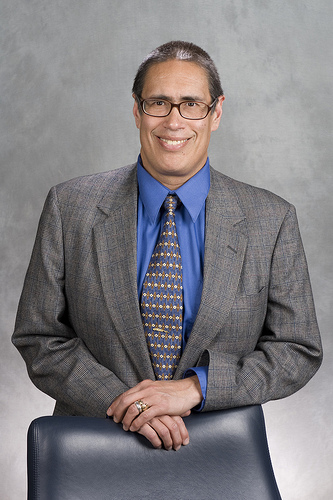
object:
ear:
[133, 101, 141, 129]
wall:
[0, 2, 330, 497]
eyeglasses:
[135, 95, 218, 120]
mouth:
[154, 134, 194, 150]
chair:
[26, 405, 280, 499]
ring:
[135, 401, 143, 412]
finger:
[113, 389, 145, 423]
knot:
[164, 195, 177, 212]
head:
[133, 41, 225, 176]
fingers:
[107, 381, 143, 416]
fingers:
[171, 415, 189, 445]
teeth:
[160, 137, 187, 145]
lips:
[156, 136, 191, 150]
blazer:
[12, 159, 324, 417]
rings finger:
[123, 397, 152, 431]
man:
[11, 40, 322, 452]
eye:
[186, 103, 197, 108]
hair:
[131, 41, 224, 116]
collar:
[137, 153, 210, 225]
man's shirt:
[135, 152, 210, 412]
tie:
[139, 195, 182, 381]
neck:
[144, 169, 202, 188]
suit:
[10, 153, 322, 418]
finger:
[138, 423, 162, 450]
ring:
[138, 400, 148, 412]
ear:
[210, 94, 225, 131]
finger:
[129, 405, 155, 432]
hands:
[137, 410, 191, 451]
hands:
[107, 379, 193, 432]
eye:
[154, 102, 165, 106]